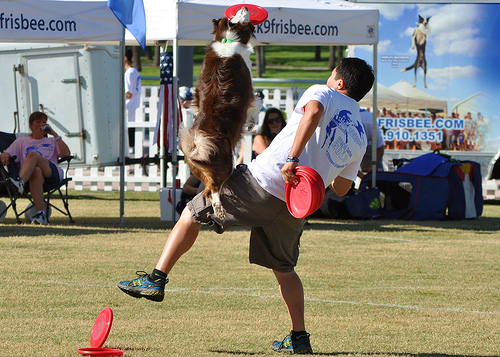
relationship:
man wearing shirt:
[233, 41, 381, 357] [259, 89, 361, 208]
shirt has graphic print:
[259, 89, 361, 208] [327, 107, 365, 170]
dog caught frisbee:
[155, 8, 276, 217] [225, 4, 267, 26]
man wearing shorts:
[233, 41, 381, 357] [200, 175, 304, 290]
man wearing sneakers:
[233, 41, 381, 357] [119, 273, 169, 305]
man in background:
[124, 47, 151, 127] [66, 25, 194, 143]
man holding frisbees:
[233, 41, 381, 357] [284, 166, 334, 219]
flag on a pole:
[152, 38, 187, 190] [160, 109, 167, 199]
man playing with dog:
[233, 41, 381, 357] [155, 8, 276, 217]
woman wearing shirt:
[5, 109, 80, 224] [8, 135, 68, 170]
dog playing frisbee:
[155, 8, 276, 217] [225, 4, 267, 26]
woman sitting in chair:
[5, 109, 80, 224] [0, 128, 25, 213]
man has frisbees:
[233, 41, 381, 357] [284, 166, 334, 219]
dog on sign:
[400, 14, 435, 92] [350, 3, 499, 174]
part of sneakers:
[138, 284, 151, 285] [119, 273, 169, 305]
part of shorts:
[239, 206, 243, 207] [200, 175, 304, 290]